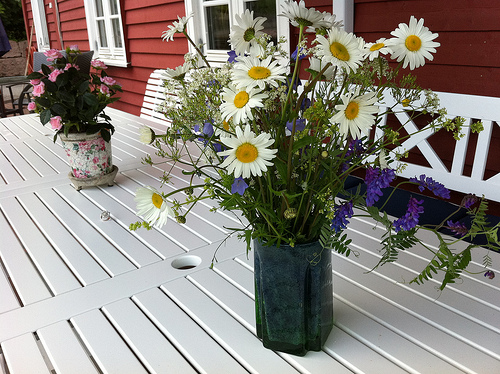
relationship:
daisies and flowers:
[141, 6, 448, 176] [134, 2, 497, 237]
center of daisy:
[329, 40, 348, 59] [314, 25, 367, 80]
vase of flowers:
[247, 230, 349, 353] [134, 2, 497, 237]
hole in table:
[171, 254, 200, 275] [6, 98, 500, 373]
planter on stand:
[57, 120, 113, 181] [68, 168, 119, 194]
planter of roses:
[67, 128, 113, 176] [23, 35, 128, 145]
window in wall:
[87, 3, 128, 66] [25, 2, 497, 164]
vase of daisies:
[247, 230, 349, 353] [141, 6, 448, 176]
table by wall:
[6, 98, 500, 373] [25, 2, 497, 164]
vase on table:
[247, 230, 349, 353] [6, 98, 500, 373]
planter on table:
[57, 120, 113, 181] [6, 98, 500, 373]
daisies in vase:
[141, 6, 448, 176] [247, 230, 349, 353]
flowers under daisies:
[134, 2, 497, 237] [141, 6, 448, 176]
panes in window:
[94, 3, 124, 54] [87, 3, 128, 66]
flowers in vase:
[134, 2, 497, 237] [247, 230, 349, 353]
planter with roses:
[57, 120, 113, 181] [23, 35, 128, 145]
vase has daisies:
[247, 230, 349, 353] [141, 6, 448, 176]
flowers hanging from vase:
[134, 2, 497, 237] [247, 230, 349, 353]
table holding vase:
[6, 98, 500, 373] [247, 230, 349, 353]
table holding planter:
[6, 98, 500, 373] [57, 120, 113, 181]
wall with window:
[25, 2, 497, 164] [87, 3, 128, 66]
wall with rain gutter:
[25, 2, 497, 164] [328, 6, 354, 78]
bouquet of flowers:
[135, 5, 499, 364] [134, 2, 497, 237]